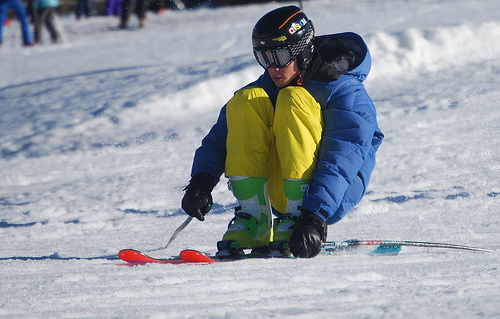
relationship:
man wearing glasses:
[180, 5, 383, 260] [252, 26, 315, 69]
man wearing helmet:
[180, 5, 383, 260] [249, 3, 316, 71]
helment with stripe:
[250, 6, 321, 74] [260, 10, 309, 24]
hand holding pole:
[159, 185, 219, 222] [127, 207, 199, 268]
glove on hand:
[167, 179, 224, 213] [175, 174, 235, 224]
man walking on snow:
[32, 0, 64, 45] [13, 66, 76, 108]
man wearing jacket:
[180, 5, 383, 260] [190, 63, 338, 213]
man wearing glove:
[180, 5, 383, 260] [289, 209, 327, 258]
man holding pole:
[180, 5, 383, 260] [163, 216, 194, 249]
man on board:
[180, 5, 383, 260] [126, 237, 386, 297]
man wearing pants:
[180, 5, 383, 260] [216, 94, 330, 243]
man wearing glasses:
[180, 5, 383, 260] [234, 29, 319, 79]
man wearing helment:
[218, 51, 385, 260] [252, 22, 317, 72]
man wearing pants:
[28, 2, 67, 60] [28, 9, 63, 49]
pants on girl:
[207, 79, 318, 247] [180, 24, 372, 235]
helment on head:
[250, 6, 321, 74] [258, 45, 343, 85]